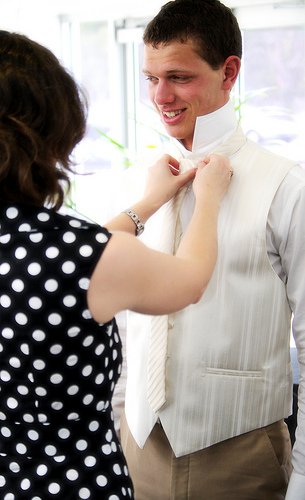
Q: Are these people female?
A: No, they are both male and female.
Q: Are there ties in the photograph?
A: Yes, there is a tie.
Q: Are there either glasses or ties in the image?
A: Yes, there is a tie.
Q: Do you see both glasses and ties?
A: No, there is a tie but no glasses.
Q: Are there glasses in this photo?
A: No, there are no glasses.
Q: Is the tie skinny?
A: Yes, the tie is skinny.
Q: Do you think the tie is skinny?
A: Yes, the tie is skinny.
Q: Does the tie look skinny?
A: Yes, the tie is skinny.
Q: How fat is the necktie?
A: The necktie is skinny.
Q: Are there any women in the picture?
A: Yes, there is a woman.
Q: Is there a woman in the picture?
A: Yes, there is a woman.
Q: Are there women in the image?
A: Yes, there is a woman.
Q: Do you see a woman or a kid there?
A: Yes, there is a woman.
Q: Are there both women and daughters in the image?
A: No, there is a woman but no daughters.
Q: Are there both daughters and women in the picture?
A: No, there is a woman but no daughters.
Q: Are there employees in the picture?
A: No, there are no employees.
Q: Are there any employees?
A: No, there are no employees.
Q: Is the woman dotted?
A: Yes, the woman is dotted.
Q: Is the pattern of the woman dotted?
A: Yes, the woman is dotted.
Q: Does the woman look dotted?
A: Yes, the woman is dotted.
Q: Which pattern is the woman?
A: The woman is dotted.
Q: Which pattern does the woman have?
A: The woman has dotted pattern.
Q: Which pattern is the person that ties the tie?
A: The woman is dotted.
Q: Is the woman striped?
A: No, the woman is dotted.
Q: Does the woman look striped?
A: No, the woman is dotted.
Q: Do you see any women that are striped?
A: No, there is a woman but she is dotted.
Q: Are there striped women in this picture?
A: No, there is a woman but she is dotted.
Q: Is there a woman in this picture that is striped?
A: No, there is a woman but she is dotted.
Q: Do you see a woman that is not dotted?
A: No, there is a woman but she is dotted.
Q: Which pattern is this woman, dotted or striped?
A: The woman is dotted.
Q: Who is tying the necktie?
A: The woman is tying the necktie.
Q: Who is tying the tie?
A: The woman is tying the necktie.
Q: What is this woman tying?
A: The woman is tying the tie.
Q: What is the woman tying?
A: The woman is tying the tie.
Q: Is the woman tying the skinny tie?
A: Yes, the woman is tying the necktie.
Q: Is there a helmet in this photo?
A: No, there are no helmets.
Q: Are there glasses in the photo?
A: No, there are no glasses.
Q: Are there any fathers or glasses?
A: No, there are no glasses or fathers.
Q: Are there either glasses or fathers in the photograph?
A: No, there are no glasses or fathers.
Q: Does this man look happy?
A: Yes, the man is happy.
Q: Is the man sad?
A: No, the man is happy.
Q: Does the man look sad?
A: No, the man is happy.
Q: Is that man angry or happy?
A: The man is happy.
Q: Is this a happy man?
A: Yes, this is a happy man.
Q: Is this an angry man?
A: No, this is a happy man.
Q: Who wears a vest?
A: The man wears a vest.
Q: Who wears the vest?
A: The man wears a vest.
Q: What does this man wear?
A: The man wears a vest.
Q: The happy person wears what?
A: The man wears a vest.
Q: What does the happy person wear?
A: The man wears a vest.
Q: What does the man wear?
A: The man wears a vest.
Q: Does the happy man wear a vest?
A: Yes, the man wears a vest.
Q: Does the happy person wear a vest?
A: Yes, the man wears a vest.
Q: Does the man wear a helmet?
A: No, the man wears a vest.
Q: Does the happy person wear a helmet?
A: No, the man wears a vest.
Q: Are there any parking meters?
A: No, there are no parking meters.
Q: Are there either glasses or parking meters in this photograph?
A: No, there are no parking meters or glasses.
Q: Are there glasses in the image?
A: No, there are no glasses.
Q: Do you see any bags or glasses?
A: No, there are no glasses or bags.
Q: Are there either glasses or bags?
A: No, there are no glasses or bags.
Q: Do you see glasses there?
A: No, there are no glasses.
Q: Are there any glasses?
A: No, there are no glasses.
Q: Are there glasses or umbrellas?
A: No, there are no glasses or umbrellas.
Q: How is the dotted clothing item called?
A: The clothing item is a dress.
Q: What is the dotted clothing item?
A: The clothing item is a dress.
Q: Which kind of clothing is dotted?
A: The clothing is a dress.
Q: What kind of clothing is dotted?
A: The clothing is a dress.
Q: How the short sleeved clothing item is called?
A: The clothing item is a dress.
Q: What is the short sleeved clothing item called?
A: The clothing item is a dress.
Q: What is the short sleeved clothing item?
A: The clothing item is a dress.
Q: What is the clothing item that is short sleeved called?
A: The clothing item is a dress.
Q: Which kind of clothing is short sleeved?
A: The clothing is a dress.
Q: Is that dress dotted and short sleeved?
A: Yes, the dress is dotted and short sleeved.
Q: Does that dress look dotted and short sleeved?
A: Yes, the dress is dotted and short sleeved.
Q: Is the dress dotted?
A: Yes, the dress is dotted.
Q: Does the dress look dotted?
A: Yes, the dress is dotted.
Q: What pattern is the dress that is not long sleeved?
A: The dress is dotted.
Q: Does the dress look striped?
A: No, the dress is dotted.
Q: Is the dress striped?
A: No, the dress is dotted.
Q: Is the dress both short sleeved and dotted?
A: Yes, the dress is short sleeved and dotted.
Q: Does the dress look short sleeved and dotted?
A: Yes, the dress is short sleeved and dotted.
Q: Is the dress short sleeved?
A: Yes, the dress is short sleeved.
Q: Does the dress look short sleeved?
A: Yes, the dress is short sleeved.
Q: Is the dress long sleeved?
A: No, the dress is short sleeved.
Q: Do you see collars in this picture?
A: Yes, there is a collar.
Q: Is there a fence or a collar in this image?
A: Yes, there is a collar.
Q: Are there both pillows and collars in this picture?
A: No, there is a collar but no pillows.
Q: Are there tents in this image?
A: No, there are no tents.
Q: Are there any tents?
A: No, there are no tents.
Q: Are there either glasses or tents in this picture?
A: No, there are no tents or glasses.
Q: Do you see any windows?
A: Yes, there is a window.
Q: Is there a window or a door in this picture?
A: Yes, there is a window.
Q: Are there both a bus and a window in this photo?
A: No, there is a window but no buses.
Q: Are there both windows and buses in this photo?
A: No, there is a window but no buses.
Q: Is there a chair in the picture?
A: No, there are no chairs.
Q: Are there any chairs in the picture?
A: No, there are no chairs.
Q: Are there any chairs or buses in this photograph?
A: No, there are no chairs or buses.